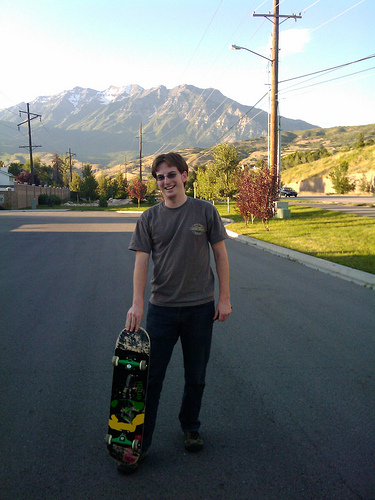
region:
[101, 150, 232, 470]
The man with the skateboard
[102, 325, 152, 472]
The skateboard held by the man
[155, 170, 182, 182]
The glasses on the man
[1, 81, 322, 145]
The mountains in the background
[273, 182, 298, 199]
The car on the road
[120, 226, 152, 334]
The arm used to hold the skateboard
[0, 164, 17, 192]
The houses in the background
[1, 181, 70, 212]
The brick fence in the background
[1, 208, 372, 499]
The street the man is standing on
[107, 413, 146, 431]
The yellow part of the skateboard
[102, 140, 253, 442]
a man holding a skateboard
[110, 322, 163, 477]
skateboard with green and yellow design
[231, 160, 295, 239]
a tree with red leaves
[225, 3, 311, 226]
street light post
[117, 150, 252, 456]
a man smiling wearing glasses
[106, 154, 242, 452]
a man wearing a black shirt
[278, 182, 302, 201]
a blue car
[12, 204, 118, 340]
a paved street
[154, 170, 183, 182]
a pair of glasses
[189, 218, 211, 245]
the logo of his shirt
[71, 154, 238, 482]
guy standing in the street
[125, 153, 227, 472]
guy wearing a grey shirt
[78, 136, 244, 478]
guy holding a skateboard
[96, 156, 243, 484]
guy wearing jeans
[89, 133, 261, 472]
guy wearing transitional glasses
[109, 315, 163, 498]
skateboard sitting on top a foot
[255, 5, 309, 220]
tall power pole on side of street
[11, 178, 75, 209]
tall fence along the road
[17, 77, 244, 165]
mountain in the background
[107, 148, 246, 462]
a man wearing glasses, tshirt, and jeans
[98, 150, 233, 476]
Man standing in the middle of the road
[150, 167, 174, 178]
Dark sunglasses on man's face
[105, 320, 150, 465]
Skateboard with the bottom facing camera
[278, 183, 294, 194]
Black car in the distance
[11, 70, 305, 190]
Mountain in the background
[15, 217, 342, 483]
Empty Road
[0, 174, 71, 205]
a wall close to the road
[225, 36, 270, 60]
Streetlight on an electric pole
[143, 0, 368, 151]
Power lines running along the road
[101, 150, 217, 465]
Man holding skateboard in the middle of the road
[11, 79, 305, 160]
mountains with snow on the top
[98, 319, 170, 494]
black yellow and green skateboard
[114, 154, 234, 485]
man in the middle of the road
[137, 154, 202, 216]
man wearing black sunglasses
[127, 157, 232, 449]
man wearing grey tee shirt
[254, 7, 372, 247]
tall pole with power lines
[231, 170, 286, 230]
bush with red leaves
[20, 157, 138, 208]
group of trees with green leaves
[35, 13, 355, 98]
bright blue sky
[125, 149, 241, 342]
smiling man with brown hair